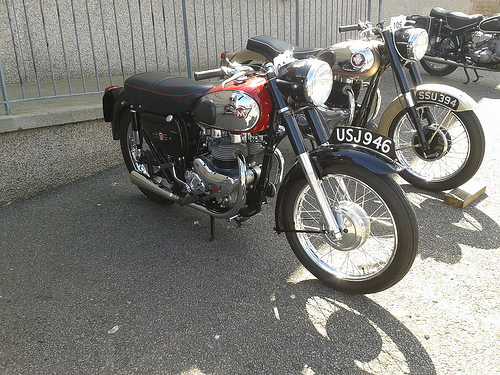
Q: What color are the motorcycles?
A: Gold, red, and black.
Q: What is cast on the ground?
A: Shadows.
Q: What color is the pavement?
A: Gray.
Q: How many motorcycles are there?
A: Three.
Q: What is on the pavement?
A: The motorcycles.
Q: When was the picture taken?
A: Daytime.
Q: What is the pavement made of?
A: Cement.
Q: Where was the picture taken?
A: In a parking lot.